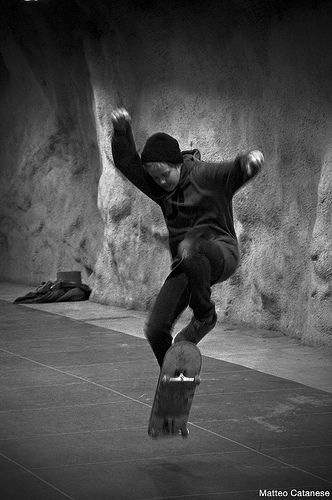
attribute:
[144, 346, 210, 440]
skateboard — grey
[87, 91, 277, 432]
boy — skating, white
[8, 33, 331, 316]
wall — white, grey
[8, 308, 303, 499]
floor — black